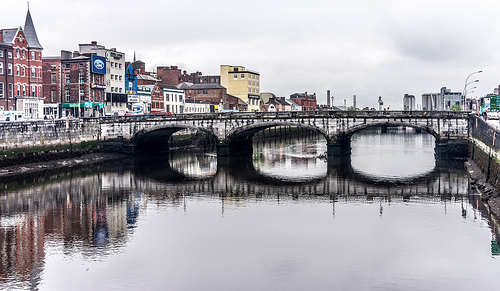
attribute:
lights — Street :
[457, 66, 481, 112]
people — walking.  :
[40, 79, 125, 129]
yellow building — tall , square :
[220, 62, 262, 109]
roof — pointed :
[20, 0, 42, 50]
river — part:
[332, 179, 438, 230]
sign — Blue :
[88, 53, 108, 77]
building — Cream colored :
[219, 59, 269, 115]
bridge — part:
[97, 105, 474, 175]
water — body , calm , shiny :
[3, 124, 495, 286]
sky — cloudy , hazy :
[299, 12, 441, 101]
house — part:
[285, 84, 320, 112]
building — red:
[11, 30, 42, 104]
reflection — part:
[74, 194, 145, 247]